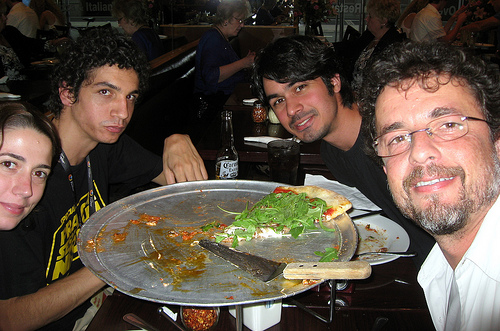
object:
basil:
[200, 190, 337, 243]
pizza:
[220, 175, 352, 239]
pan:
[78, 177, 361, 307]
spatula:
[197, 239, 374, 286]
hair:
[348, 40, 500, 129]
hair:
[254, 34, 347, 86]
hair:
[57, 35, 143, 104]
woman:
[1, 114, 64, 276]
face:
[0, 125, 55, 232]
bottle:
[214, 103, 248, 182]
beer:
[216, 112, 242, 183]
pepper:
[183, 308, 214, 330]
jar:
[179, 306, 219, 330]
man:
[356, 31, 500, 330]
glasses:
[373, 114, 488, 158]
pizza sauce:
[82, 209, 215, 284]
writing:
[40, 188, 102, 286]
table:
[89, 145, 434, 331]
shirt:
[2, 114, 152, 301]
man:
[16, 41, 218, 331]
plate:
[347, 208, 412, 269]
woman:
[194, 1, 259, 92]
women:
[363, 0, 409, 69]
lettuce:
[312, 244, 343, 265]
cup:
[265, 138, 305, 186]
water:
[274, 150, 300, 182]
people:
[0, 97, 69, 330]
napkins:
[302, 173, 382, 222]